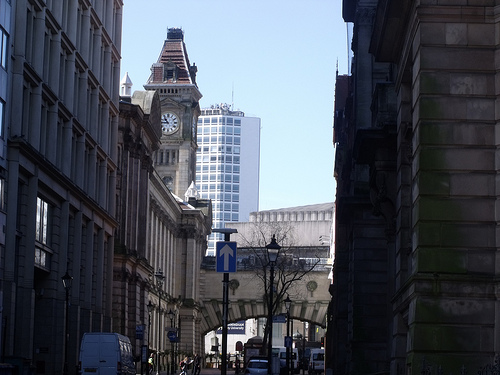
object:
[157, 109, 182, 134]
clock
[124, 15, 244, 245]
building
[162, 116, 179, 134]
hands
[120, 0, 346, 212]
sky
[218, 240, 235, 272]
road sign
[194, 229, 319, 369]
streetlight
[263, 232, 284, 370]
lamp post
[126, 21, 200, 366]
tower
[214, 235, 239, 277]
sign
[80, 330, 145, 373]
van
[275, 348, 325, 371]
traffic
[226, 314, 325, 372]
archway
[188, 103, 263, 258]
building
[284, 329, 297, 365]
van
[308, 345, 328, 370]
van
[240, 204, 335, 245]
building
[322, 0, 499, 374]
building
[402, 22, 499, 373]
siding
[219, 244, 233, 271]
arrow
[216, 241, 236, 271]
background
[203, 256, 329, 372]
cement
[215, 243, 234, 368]
pole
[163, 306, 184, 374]
lamp post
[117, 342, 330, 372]
street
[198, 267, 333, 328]
bridge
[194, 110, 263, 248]
highrise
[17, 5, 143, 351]
building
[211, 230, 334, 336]
overhang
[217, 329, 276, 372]
vehicle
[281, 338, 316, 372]
vehicle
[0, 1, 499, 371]
city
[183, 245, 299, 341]
carving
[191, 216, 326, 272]
train